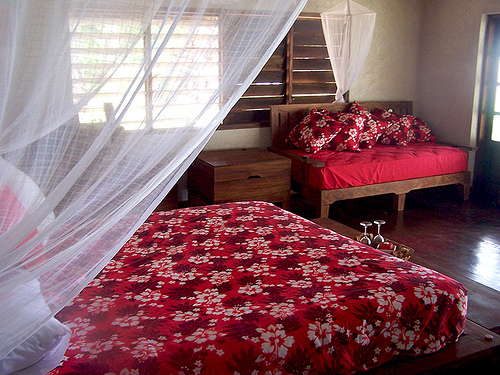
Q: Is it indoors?
A: Yes, it is indoors.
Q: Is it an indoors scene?
A: Yes, it is indoors.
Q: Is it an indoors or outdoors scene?
A: It is indoors.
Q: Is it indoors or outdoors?
A: It is indoors.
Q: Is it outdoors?
A: No, it is indoors.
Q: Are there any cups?
A: No, there are no cups.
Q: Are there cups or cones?
A: No, there are no cups or cones.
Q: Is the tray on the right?
A: Yes, the tray is on the right of the image.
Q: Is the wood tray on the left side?
A: No, the tray is on the right of the image.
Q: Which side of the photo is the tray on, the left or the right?
A: The tray is on the right of the image.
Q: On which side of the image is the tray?
A: The tray is on the right of the image.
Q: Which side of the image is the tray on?
A: The tray is on the right of the image.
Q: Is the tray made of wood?
A: Yes, the tray is made of wood.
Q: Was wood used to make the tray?
A: Yes, the tray is made of wood.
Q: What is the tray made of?
A: The tray is made of wood.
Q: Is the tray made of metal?
A: No, the tray is made of wood.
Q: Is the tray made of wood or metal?
A: The tray is made of wood.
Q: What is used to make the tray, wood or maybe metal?
A: The tray is made of wood.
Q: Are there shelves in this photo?
A: No, there are no shelves.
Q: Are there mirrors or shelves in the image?
A: No, there are no shelves or mirrors.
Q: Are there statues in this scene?
A: No, there are no statues.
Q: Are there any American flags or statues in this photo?
A: No, there are no statues or American flags.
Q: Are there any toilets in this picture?
A: No, there are no toilets.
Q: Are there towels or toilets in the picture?
A: No, there are no toilets or towels.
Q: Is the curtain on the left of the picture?
A: Yes, the curtain is on the left of the image.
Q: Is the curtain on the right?
A: No, the curtain is on the left of the image.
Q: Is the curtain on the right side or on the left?
A: The curtain is on the left of the image.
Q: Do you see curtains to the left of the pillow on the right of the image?
A: Yes, there is a curtain to the left of the pillow.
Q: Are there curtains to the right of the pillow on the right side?
A: No, the curtain is to the left of the pillow.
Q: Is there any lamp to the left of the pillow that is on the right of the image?
A: No, there is a curtain to the left of the pillow.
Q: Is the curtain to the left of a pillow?
A: Yes, the curtain is to the left of a pillow.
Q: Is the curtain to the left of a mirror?
A: No, the curtain is to the left of a pillow.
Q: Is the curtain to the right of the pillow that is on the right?
A: No, the curtain is to the left of the pillow.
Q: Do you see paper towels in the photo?
A: No, there are no paper towels.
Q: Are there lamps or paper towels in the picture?
A: No, there are no paper towels or lamps.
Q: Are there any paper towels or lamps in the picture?
A: No, there are no paper towels or lamps.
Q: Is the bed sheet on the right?
A: Yes, the bed sheet is on the right of the image.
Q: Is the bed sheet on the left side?
A: No, the bed sheet is on the right of the image.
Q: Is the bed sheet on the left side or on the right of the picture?
A: The bed sheet is on the right of the image.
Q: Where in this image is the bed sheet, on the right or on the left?
A: The bed sheet is on the right of the image.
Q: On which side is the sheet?
A: The sheet is on the right of the image.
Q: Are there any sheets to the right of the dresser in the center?
A: Yes, there is a sheet to the right of the dresser.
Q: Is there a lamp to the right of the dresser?
A: No, there is a sheet to the right of the dresser.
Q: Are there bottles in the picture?
A: No, there are no bottles.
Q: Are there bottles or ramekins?
A: No, there are no bottles or ramekins.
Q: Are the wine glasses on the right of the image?
A: Yes, the wine glasses are on the right of the image.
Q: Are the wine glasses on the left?
A: No, the wine glasses are on the right of the image.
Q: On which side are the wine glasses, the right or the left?
A: The wine glasses are on the right of the image.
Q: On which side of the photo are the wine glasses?
A: The wine glasses are on the right of the image.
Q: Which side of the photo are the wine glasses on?
A: The wine glasses are on the right of the image.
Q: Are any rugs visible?
A: No, there are no rugs.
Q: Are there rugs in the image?
A: No, there are no rugs.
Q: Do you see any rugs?
A: No, there are no rugs.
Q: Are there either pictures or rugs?
A: No, there are no rugs or pictures.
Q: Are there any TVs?
A: No, there are no tvs.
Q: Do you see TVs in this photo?
A: No, there are no tvs.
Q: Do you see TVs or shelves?
A: No, there are no TVs or shelves.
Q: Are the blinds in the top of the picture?
A: Yes, the blinds are in the top of the image.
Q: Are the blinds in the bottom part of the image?
A: No, the blinds are in the top of the image.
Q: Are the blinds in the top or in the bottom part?
A: The blinds are in the top of the image.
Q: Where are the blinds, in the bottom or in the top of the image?
A: The blinds are in the top of the image.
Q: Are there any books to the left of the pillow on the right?
A: No, there are blinds to the left of the pillow.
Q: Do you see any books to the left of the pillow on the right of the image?
A: No, there are blinds to the left of the pillow.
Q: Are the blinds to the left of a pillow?
A: Yes, the blinds are to the left of a pillow.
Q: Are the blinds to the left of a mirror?
A: No, the blinds are to the left of a pillow.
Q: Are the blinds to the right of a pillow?
A: No, the blinds are to the left of a pillow.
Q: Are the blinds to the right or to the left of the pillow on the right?
A: The blinds are to the left of the pillow.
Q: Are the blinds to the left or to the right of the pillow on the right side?
A: The blinds are to the left of the pillow.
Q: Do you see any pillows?
A: Yes, there is a pillow.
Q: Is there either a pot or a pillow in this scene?
A: Yes, there is a pillow.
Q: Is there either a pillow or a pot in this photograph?
A: Yes, there is a pillow.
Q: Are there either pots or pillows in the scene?
A: Yes, there is a pillow.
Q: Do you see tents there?
A: No, there are no tents.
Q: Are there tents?
A: No, there are no tents.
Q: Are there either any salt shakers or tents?
A: No, there are no tents or salt shakers.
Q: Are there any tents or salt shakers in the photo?
A: No, there are no tents or salt shakers.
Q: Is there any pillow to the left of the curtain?
A: No, the pillow is to the right of the curtain.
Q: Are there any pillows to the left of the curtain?
A: No, the pillow is to the right of the curtain.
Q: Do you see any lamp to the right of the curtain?
A: No, there is a pillow to the right of the curtain.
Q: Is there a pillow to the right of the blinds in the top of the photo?
A: Yes, there is a pillow to the right of the blinds.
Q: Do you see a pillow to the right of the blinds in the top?
A: Yes, there is a pillow to the right of the blinds.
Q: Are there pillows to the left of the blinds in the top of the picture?
A: No, the pillow is to the right of the blinds.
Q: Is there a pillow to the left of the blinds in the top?
A: No, the pillow is to the right of the blinds.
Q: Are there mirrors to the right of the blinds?
A: No, there is a pillow to the right of the blinds.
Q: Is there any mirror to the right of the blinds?
A: No, there is a pillow to the right of the blinds.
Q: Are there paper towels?
A: No, there are no paper towels.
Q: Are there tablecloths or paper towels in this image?
A: No, there are no paper towels or tablecloths.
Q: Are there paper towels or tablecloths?
A: No, there are no paper towels or tablecloths.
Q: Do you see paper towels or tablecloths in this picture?
A: No, there are no paper towels or tablecloths.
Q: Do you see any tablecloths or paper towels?
A: No, there are no paper towels or tablecloths.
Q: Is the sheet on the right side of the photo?
A: Yes, the sheet is on the right of the image.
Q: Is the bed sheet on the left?
A: No, the bed sheet is on the right of the image.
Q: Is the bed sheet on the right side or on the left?
A: The bed sheet is on the right of the image.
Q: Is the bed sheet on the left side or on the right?
A: The bed sheet is on the right of the image.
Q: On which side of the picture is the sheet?
A: The sheet is on the right of the image.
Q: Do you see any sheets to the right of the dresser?
A: Yes, there is a sheet to the right of the dresser.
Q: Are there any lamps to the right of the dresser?
A: No, there is a sheet to the right of the dresser.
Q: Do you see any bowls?
A: No, there are no bowls.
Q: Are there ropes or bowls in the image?
A: No, there are no bowls or ropes.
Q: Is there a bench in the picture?
A: Yes, there is a bench.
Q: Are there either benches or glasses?
A: Yes, there is a bench.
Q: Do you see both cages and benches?
A: No, there is a bench but no cages.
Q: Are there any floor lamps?
A: No, there are no floor lamps.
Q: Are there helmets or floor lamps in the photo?
A: No, there are no floor lamps or helmets.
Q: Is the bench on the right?
A: Yes, the bench is on the right of the image.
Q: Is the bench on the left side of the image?
A: No, the bench is on the right of the image.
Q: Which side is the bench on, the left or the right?
A: The bench is on the right of the image.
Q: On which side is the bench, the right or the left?
A: The bench is on the right of the image.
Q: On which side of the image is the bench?
A: The bench is on the right of the image.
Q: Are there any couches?
A: Yes, there is a couch.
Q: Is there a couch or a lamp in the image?
A: Yes, there is a couch.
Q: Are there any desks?
A: No, there are no desks.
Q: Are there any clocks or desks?
A: No, there are no desks or clocks.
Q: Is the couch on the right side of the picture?
A: Yes, the couch is on the right of the image.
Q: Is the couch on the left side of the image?
A: No, the couch is on the right of the image.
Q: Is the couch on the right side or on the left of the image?
A: The couch is on the right of the image.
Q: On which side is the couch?
A: The couch is on the right of the image.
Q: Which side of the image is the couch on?
A: The couch is on the right of the image.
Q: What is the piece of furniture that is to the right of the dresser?
A: The piece of furniture is a couch.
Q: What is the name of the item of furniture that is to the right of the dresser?
A: The piece of furniture is a couch.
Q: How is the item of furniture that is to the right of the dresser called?
A: The piece of furniture is a couch.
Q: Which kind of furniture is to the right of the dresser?
A: The piece of furniture is a couch.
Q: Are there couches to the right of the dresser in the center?
A: Yes, there is a couch to the right of the dresser.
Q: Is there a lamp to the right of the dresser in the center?
A: No, there is a couch to the right of the dresser.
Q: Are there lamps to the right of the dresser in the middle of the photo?
A: No, there is a couch to the right of the dresser.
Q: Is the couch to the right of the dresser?
A: Yes, the couch is to the right of the dresser.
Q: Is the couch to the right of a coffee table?
A: No, the couch is to the right of the dresser.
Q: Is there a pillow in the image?
A: Yes, there are pillows.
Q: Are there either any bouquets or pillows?
A: Yes, there are pillows.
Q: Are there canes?
A: No, there are no canes.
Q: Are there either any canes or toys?
A: No, there are no canes or toys.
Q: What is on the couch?
A: The pillows are on the couch.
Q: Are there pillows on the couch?
A: Yes, there are pillows on the couch.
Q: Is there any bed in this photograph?
A: Yes, there is a bed.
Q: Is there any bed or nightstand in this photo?
A: Yes, there is a bed.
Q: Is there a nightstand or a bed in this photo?
A: Yes, there is a bed.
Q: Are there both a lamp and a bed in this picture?
A: No, there is a bed but no lamps.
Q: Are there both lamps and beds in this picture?
A: No, there is a bed but no lamps.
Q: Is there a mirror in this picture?
A: No, there are no mirrors.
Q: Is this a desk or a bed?
A: This is a bed.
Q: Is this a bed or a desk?
A: This is a bed.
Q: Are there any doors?
A: Yes, there is a door.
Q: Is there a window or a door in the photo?
A: Yes, there is a door.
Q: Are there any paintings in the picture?
A: No, there are no paintings.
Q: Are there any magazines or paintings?
A: No, there are no paintings or magazines.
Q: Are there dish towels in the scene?
A: No, there are no dish towels.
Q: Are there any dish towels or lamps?
A: No, there are no dish towels or lamps.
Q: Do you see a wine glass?
A: Yes, there is a wine glass.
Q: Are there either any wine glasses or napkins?
A: Yes, there is a wine glass.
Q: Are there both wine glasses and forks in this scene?
A: No, there is a wine glass but no forks.